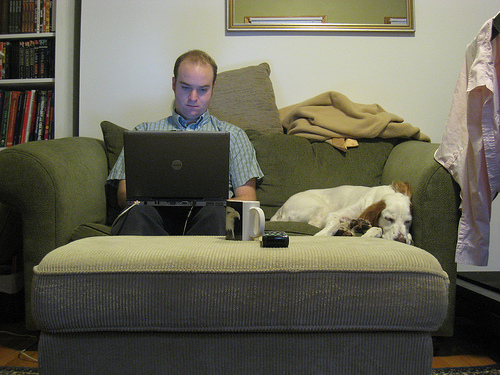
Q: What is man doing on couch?
A: On his laptop.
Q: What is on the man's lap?
A: Laptop.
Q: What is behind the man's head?
A: Pillow.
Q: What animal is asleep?
A: Dog.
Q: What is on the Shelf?
A: Books.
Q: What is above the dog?
A: Blanket.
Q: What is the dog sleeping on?
A: Couch.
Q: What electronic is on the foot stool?
A: Remote.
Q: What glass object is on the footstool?
A: Coffee cup.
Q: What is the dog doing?
A: Sleeping.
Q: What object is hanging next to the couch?
A: Shirt.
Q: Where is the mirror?
A: On wall.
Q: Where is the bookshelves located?
A: Left side of wall.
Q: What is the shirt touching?
A: Arm of couch.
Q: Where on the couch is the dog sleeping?
A: Right corner.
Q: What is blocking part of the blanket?
A: Green pillow.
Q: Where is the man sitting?
A: On couch.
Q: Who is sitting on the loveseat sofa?
A: A man.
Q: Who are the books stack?
A: Top, middle and bottom.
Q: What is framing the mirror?
A: Brown wooden trimming.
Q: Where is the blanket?
A: On couch.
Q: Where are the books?
A: On bookshelf.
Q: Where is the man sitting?
A: On couch.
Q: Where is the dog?
A: On couch.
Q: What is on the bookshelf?
A: Books.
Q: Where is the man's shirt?
A: On hanger.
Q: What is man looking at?
A: Laptop.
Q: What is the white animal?
A: Dog.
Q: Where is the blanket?
A: On couch.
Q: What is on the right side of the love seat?
A: Dog.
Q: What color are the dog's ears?
A: Brown.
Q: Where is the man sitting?
A: Left side.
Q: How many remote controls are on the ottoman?
A: One.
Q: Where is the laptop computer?
A: Man's lap.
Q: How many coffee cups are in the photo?
A: One.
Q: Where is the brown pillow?
A: Top back of the love seat.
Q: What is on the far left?
A: Bookcase.